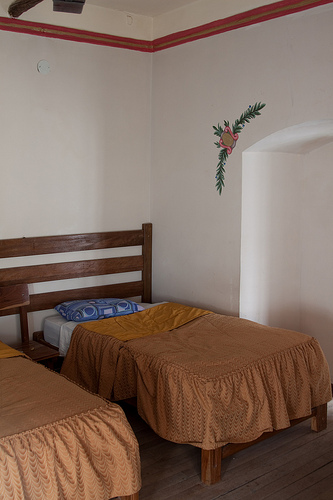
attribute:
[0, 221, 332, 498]
beds — wooden, wood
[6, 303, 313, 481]
sheets — brown, gold, orange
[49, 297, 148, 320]
pillow — blue, patterned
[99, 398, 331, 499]
floor — brown, wood, hard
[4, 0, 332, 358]
walls — white, bright, striped, bordered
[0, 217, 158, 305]
headboard — wooden, brown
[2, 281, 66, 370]
chair — wooden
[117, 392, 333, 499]
legs — wood, wooden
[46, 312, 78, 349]
sheet — white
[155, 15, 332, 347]
wall — idented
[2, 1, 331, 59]
boarder — red, gold